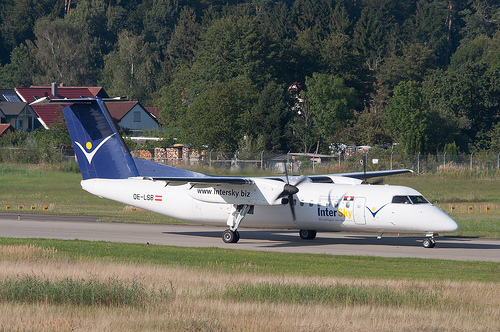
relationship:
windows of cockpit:
[389, 190, 430, 205] [359, 175, 465, 242]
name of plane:
[313, 201, 359, 231] [48, 90, 459, 248]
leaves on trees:
[173, 0, 495, 131] [1, 6, 496, 158]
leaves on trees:
[348, 20, 480, 131] [106, 22, 487, 180]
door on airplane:
[351, 196, 367, 224] [34, 83, 460, 248]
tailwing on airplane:
[29, 92, 134, 109] [34, 83, 460, 248]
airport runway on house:
[1, 208, 498, 263] [101, 97, 173, 138]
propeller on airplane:
[273, 149, 308, 216] [34, 83, 460, 248]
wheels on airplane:
[290, 222, 317, 237] [24, 82, 476, 274]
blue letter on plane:
[211, 182, 216, 194] [48, 90, 459, 248]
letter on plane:
[320, 209, 325, 218] [21, 82, 459, 247]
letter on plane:
[318, 208, 326, 220] [30, 88, 470, 259]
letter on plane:
[315, 205, 323, 218] [21, 82, 459, 247]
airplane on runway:
[28, 83, 460, 248] [0, 210, 497, 261]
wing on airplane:
[133, 163, 280, 201] [22, 67, 491, 259]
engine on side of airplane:
[185, 177, 299, 210] [22, 67, 491, 259]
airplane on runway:
[34, 83, 460, 248] [0, 210, 497, 261]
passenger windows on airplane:
[316, 198, 323, 205] [47, 95, 459, 249]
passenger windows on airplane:
[307, 197, 314, 208] [47, 95, 459, 249]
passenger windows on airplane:
[298, 196, 305, 206] [47, 95, 459, 249]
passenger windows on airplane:
[290, 197, 296, 204] [47, 95, 459, 249]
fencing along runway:
[73, 147, 498, 174] [0, 210, 497, 261]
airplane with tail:
[28, 83, 460, 248] [26, 87, 140, 177]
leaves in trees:
[173, 0, 495, 131] [298, 3, 484, 151]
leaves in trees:
[173, 0, 495, 131] [241, 10, 499, 158]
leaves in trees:
[173, 0, 495, 131] [1, 6, 496, 158]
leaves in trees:
[173, 0, 495, 131] [329, 12, 488, 160]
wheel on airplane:
[223, 230, 238, 242] [34, 83, 460, 248]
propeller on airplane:
[275, 160, 307, 221] [34, 83, 460, 248]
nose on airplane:
[420, 208, 465, 250] [28, 83, 460, 248]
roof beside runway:
[28, 95, 139, 131] [0, 210, 497, 261]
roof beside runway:
[13, 86, 94, 102] [0, 210, 497, 261]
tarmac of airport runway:
[73, 215, 438, 258] [3, 208, 498, 261]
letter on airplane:
[194, 184, 202, 196] [28, 83, 460, 248]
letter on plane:
[200, 187, 208, 197] [196, 185, 251, 198]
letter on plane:
[239, 189, 245, 202] [18, 78, 465, 270]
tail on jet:
[23, 90, 144, 179] [28, 52, 480, 289]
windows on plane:
[391, 195, 411, 203] [48, 90, 459, 248]